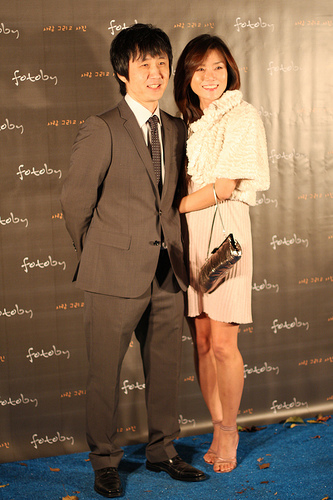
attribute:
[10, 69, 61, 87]
word — white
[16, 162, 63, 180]
word — white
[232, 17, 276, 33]
word — white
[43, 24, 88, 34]
word — gold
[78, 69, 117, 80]
word — gold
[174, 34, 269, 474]
woman — posing, smiling, well dressed, asian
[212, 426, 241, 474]
shoe — clear, beige, ankle strapped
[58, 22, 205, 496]
man — posing, smiling, well dressed, asian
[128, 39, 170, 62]
bangs — black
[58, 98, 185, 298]
jacket — brown, single breasted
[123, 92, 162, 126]
collar — white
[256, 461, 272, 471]
leaf — small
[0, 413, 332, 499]
floor — blue, outdoor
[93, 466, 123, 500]
shoe — black, leather, shiny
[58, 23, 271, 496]
couple — posing, standing, attractive, beautiful, well dressed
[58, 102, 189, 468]
suit — brown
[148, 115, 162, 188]
tie — brown, dotted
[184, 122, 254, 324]
dress — beige, pleated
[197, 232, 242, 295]
purse — silver, metallic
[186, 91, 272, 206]
cape — cream, short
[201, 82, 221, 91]
smile — bright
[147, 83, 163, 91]
smile — bright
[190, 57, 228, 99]
face — smiling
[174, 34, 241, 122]
hair — brown